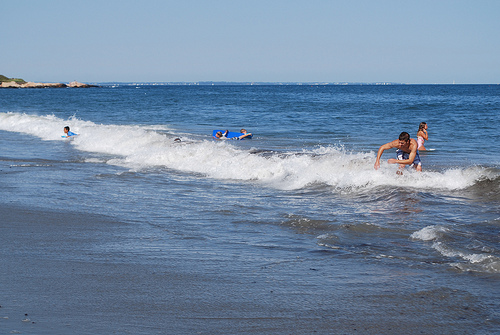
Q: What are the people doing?
A: Surfing.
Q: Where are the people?
A: In the water.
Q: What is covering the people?
A: A wave.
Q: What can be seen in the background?
A: The sky.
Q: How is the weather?
A: Sunny.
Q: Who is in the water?
A: Person swimming and surfing.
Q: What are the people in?
A: Body of water.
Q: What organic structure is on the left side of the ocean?
A: Brown mountain.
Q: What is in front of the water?
A: Wet sand.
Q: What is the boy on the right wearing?
A: Swim trunks.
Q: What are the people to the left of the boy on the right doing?
A: Floating with blue water toy.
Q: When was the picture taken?
A: Daytime.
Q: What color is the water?
A: Blue water.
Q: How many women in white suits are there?
A: One.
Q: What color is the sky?
A: Blue.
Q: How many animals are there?
A: None.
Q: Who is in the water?
A: The people are.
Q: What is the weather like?
A: Sunny.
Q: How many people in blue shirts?
A: One person.